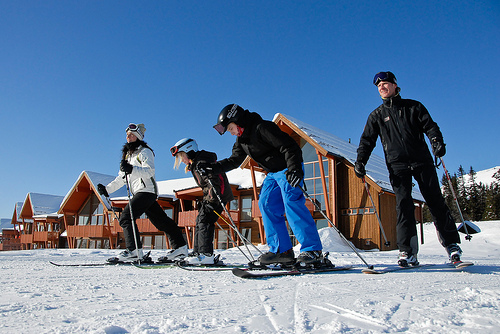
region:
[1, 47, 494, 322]
A family is skiing together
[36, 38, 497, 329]
A family is enjoying their vacation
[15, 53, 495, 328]
A family is at a ski lodge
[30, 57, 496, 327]
A father is taking his family to ski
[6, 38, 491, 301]
Children are skiing with their parents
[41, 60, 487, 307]
A mother is skiing with her family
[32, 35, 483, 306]
Skiers are going down the slopes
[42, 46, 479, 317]
People are having fun today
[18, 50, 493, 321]
The sky is bright over the skiers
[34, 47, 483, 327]
The family is skiing in daytime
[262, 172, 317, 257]
Bright blue ski pants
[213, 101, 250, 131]
Black helmet on skier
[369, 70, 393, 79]
Black goggles on skier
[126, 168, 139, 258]
Silver ski pole in skier's hand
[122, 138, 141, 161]
Fuzzy black scarf on skier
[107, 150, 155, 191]
White jacket on skier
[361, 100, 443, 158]
Black jacket on skier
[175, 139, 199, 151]
Light blue helmet on skier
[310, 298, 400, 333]
Ski tracks in snow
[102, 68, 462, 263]
Group of skiers on snow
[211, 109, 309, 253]
young boy skiing in white snow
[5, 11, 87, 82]
white clouds against blue sky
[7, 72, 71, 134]
white clouds against blue sky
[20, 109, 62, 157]
white clouds against blue sky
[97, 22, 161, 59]
white clouds against blue sky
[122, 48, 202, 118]
white clouds against blue sky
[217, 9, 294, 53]
white clouds against blue sky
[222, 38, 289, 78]
white clouds against blue sky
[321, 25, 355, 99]
white clouds against blue sky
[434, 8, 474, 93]
white clouds against blue sky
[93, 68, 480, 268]
four skiers in front of a lodge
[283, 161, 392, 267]
ski poles in skier's hands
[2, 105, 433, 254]
lodge rooms for the skiers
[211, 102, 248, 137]
helmet with goggles attached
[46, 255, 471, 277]
row of skies on the skiers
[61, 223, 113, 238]
balcony of one of the lodge rooms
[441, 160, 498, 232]
evergreen trees in the background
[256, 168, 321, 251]
bright blue ski pants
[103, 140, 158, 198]
black and white ski jacket with fur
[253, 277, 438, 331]
ski tracks in the snow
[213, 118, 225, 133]
goggles on boy's head.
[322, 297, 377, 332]
ski tracks in the snow.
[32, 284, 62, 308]
snow on the ground.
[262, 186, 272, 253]
blue pant leg on boy.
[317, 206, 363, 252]
ski pole in boy's hand.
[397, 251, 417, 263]
ski boot on man's foot.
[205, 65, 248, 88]
blue sky above lodge.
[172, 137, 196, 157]
helmet on the girl.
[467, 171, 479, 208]
pine tree behind lodge.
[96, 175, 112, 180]
snow on the roof.